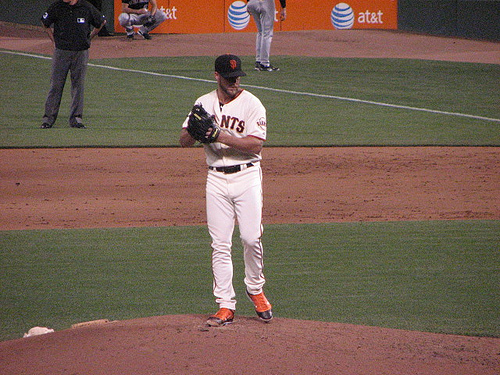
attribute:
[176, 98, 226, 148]
glove. —  for  baseball 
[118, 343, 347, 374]
pitcher's mound —    clean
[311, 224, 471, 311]
grass —  Beautiful,   green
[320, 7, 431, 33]
at&t —  advertising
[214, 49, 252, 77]
cap —  for baseball,  player's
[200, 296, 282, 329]
shoes — orange and black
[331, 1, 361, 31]
logo — blue and white, at&t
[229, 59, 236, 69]
logo —  small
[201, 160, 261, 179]
belt —  black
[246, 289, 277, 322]
shoe —  bright,   pitcher's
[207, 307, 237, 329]
shoe —  bright,   pitcher's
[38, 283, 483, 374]
mound —  small,  of dirt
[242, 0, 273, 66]
pants — light grey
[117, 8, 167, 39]
pants — light grey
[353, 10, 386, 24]
print — white,  at&t